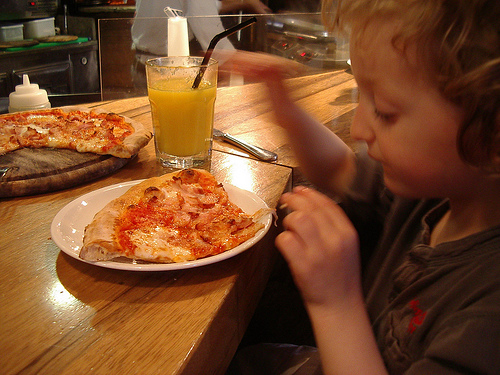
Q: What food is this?
A: Pizza.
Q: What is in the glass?
A: Orange juice.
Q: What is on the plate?
A: Pizza.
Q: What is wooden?
A: The table.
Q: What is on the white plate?
A: Pizza slice.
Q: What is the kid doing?
A: Eating.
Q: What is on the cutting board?
A: Pizza.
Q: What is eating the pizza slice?
A: The child.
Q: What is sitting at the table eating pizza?
A: The little boy.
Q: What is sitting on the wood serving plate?
A: The pizza.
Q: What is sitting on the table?
A: Glass of orange juice.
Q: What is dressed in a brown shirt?
A: The little boy.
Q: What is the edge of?
A: Brown wood table.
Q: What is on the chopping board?
A: The pizza.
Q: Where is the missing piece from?
A: The pizza.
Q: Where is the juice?
A: Next to plate.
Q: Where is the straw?
A: In glass.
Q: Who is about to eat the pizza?
A: The boy.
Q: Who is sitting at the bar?
A: The boy.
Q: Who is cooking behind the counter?
A: A man.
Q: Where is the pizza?
A: On the plate.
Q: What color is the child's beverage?
A: Yellow.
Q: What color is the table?
A: Brown.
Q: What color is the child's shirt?
A: Brown.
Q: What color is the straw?
A: Black.